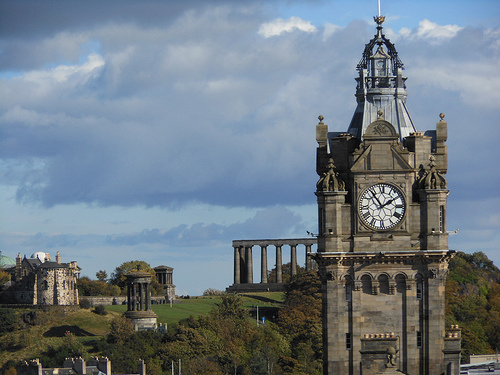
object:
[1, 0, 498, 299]
sky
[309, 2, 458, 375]
tower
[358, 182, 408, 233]
clock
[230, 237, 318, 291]
building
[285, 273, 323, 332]
tree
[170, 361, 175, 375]
chimney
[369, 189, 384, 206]
hand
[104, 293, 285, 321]
field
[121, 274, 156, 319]
pillars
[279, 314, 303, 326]
leaf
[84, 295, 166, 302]
wall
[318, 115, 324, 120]
sphere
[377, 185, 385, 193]
number